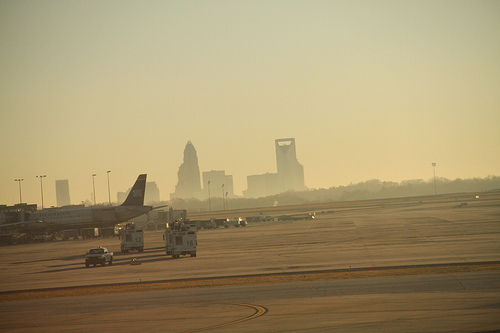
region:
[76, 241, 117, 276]
White truck with orange light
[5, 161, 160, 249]
Airplane on the tarmac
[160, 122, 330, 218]
Buildings in the distance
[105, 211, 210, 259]
Two white trucks on an airport tarmac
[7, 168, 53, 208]
Two light poles with three lights each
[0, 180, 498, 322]
Airport tarmac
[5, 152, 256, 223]
Light poles in the distance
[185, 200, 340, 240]
Airport luggage transportation trucks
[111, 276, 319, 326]
Yellow lane line on the tarmac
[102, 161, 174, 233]
Tail wing of an airplane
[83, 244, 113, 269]
white truck on runway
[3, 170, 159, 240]
airplane parked on runway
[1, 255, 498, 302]
strip of grass between runways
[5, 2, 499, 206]
sky cloudy and grey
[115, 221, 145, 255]
large white work truck near plane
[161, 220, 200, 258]
large white work truck behind other truck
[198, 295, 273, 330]
yellow semi circle line on pavement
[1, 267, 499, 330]
runway made of concrete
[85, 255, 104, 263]
black front of white truck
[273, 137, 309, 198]
tall building seen in distance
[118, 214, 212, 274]
white emergency vehicles on runway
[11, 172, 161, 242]
large plane on runway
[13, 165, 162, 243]
large white plane with red wing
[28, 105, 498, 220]
city in background against sky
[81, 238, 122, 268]
white truck with orange emergency light on top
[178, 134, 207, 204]
conical shaped building in distance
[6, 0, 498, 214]
cloudy gray overcast sky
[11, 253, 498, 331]
yellow lines on gray concrete runway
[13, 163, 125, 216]
light poles in distance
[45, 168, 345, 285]
airplane and vehicles on airport grounds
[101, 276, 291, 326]
black and yellow curve on paved ground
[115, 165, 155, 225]
dark tail over pointed end of plane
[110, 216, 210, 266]
boxy trucks headed in same direction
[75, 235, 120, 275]
large car with orange light on top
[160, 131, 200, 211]
jagged edge of building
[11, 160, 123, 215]
tall poles with lights on the top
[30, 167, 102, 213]
rectangular building between two lampposts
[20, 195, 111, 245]
vehicles in front of airplane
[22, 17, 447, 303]
airport on a hazy and overcast day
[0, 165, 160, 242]
large white plane on runway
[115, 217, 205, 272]
white emergency trucks on runway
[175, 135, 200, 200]
conical building in distance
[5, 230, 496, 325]
yellow lines on grey runway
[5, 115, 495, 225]
city in distance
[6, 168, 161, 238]
large plane with red wing on runway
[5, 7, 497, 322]
daytime outdoor airport scene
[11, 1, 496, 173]
overcast cloudy sky